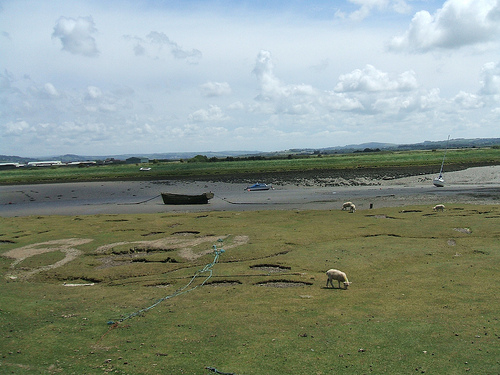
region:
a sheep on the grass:
[313, 262, 360, 297]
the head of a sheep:
[338, 275, 357, 293]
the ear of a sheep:
[349, 277, 354, 289]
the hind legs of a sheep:
[323, 277, 337, 292]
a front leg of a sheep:
[334, 278, 342, 290]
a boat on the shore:
[152, 185, 222, 216]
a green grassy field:
[3, 206, 495, 372]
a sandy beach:
[0, 163, 499, 221]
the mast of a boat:
[433, 130, 456, 179]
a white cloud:
[328, 60, 433, 100]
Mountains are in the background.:
[0, 130, 499, 176]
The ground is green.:
[239, 310, 403, 369]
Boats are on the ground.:
[137, 164, 455, 209]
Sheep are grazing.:
[309, 193, 461, 294]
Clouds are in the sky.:
[98, 22, 248, 107]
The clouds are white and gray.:
[79, 18, 243, 100]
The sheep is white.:
[315, 252, 372, 304]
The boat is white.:
[421, 156, 458, 191]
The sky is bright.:
[87, 7, 212, 109]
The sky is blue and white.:
[162, 2, 245, 52]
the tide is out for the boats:
[3, 150, 498, 237]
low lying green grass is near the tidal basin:
[6, 155, 499, 358]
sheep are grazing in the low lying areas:
[323, 195, 468, 322]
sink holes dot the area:
[33, 202, 498, 287]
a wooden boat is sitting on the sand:
[154, 187, 214, 209]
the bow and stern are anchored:
[76, 186, 283, 208]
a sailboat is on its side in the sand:
[428, 155, 450, 191]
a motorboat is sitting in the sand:
[239, 177, 276, 197]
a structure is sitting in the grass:
[133, 154, 155, 174]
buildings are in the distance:
[1, 153, 137, 230]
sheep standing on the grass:
[311, 256, 356, 296]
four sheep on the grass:
[324, 193, 485, 310]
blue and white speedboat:
[245, 178, 272, 195]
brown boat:
[156, 188, 221, 208]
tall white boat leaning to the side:
[420, 139, 462, 191]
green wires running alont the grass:
[101, 239, 255, 334]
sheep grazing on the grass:
[319, 261, 354, 293]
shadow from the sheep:
[318, 281, 348, 297]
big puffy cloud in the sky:
[390, 0, 498, 61]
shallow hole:
[247, 262, 294, 274]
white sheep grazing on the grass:
[320, 263, 353, 290]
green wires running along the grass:
[106, 233, 237, 328]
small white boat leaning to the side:
[423, 133, 457, 188]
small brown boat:
[154, 183, 219, 210]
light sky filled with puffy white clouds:
[2, 3, 499, 143]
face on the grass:
[342, 276, 353, 291]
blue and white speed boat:
[245, 182, 275, 194]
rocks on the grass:
[98, 351, 133, 368]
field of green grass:
[3, 215, 493, 374]